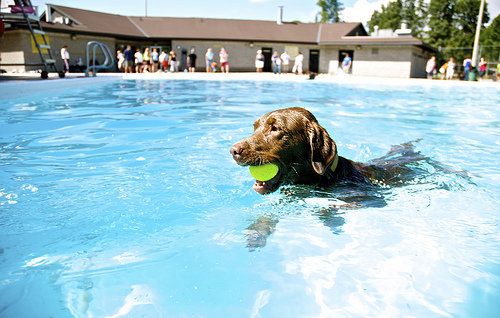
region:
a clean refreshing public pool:
[2, 70, 497, 316]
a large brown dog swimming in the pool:
[229, 105, 481, 250]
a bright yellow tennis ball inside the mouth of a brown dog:
[248, 164, 276, 181]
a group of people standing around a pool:
[116, 42, 232, 73]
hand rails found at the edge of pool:
[84, 38, 111, 75]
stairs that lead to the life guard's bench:
[0, 1, 67, 76]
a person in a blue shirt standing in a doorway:
[340, 50, 351, 72]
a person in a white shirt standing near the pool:
[57, 41, 68, 72]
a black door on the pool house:
[305, 46, 316, 71]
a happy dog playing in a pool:
[230, 101, 481, 250]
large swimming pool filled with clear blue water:
[1, 63, 498, 317]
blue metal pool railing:
[78, 40, 117, 81]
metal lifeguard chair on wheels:
[0, 1, 70, 80]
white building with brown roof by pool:
[1, 0, 439, 82]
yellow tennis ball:
[244, 151, 283, 186]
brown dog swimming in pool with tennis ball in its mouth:
[226, 99, 480, 254]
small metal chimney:
[275, 2, 286, 28]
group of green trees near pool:
[308, 0, 498, 80]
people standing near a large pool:
[111, 40, 241, 75]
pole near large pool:
[464, 0, 489, 85]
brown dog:
[222, 104, 427, 219]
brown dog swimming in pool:
[222, 105, 438, 240]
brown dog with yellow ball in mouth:
[217, 105, 353, 207]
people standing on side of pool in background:
[102, 33, 358, 83]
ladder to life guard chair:
[0, 1, 76, 87]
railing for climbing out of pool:
[80, 36, 117, 81]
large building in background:
[42, 2, 437, 82]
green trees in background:
[371, 3, 498, 70]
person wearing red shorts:
[216, 45, 232, 77]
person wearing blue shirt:
[338, 49, 354, 81]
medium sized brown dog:
[212, 97, 470, 254]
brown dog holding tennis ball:
[218, 91, 483, 267]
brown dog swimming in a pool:
[223, 99, 473, 277]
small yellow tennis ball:
[239, 156, 287, 184]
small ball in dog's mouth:
[248, 153, 287, 186]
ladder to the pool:
[78, 33, 123, 93]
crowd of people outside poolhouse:
[114, 41, 239, 81]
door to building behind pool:
[305, 43, 324, 80]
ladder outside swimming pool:
[9, 1, 65, 88]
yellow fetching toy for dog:
[244, 162, 293, 183]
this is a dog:
[225, 79, 377, 216]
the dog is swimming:
[220, 95, 357, 188]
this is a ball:
[245, 162, 278, 179]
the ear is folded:
[294, 127, 339, 170]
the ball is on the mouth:
[246, 155, 278, 182]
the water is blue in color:
[58, 135, 189, 216]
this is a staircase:
[27, 25, 49, 60]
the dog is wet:
[342, 156, 394, 185]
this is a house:
[276, 20, 323, 46]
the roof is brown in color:
[243, 22, 275, 38]